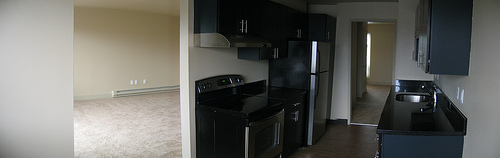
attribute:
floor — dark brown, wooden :
[278, 123, 378, 156]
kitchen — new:
[195, 0, 494, 155]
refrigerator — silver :
[267, 38, 332, 145]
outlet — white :
[130, 79, 133, 85]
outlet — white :
[133, 78, 138, 87]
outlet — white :
[141, 78, 147, 85]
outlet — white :
[458, 87, 465, 106]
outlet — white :
[454, 86, 459, 101]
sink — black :
[397, 86, 437, 110]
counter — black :
[372, 89, 473, 156]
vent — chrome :
[201, 27, 278, 63]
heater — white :
[107, 82, 184, 97]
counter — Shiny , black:
[374, 77, 466, 157]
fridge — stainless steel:
[267, 37, 333, 145]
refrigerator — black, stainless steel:
[283, 38, 331, 149]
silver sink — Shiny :
[367, 63, 451, 144]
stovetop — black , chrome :
[199, 76, 293, 137]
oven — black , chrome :
[241, 115, 298, 156]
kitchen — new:
[199, 12, 481, 144]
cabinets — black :
[218, 12, 318, 54]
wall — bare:
[76, 0, 178, 108]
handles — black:
[264, 20, 343, 150]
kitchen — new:
[191, 6, 496, 147]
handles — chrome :
[240, 17, 250, 38]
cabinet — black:
[220, 5, 277, 42]